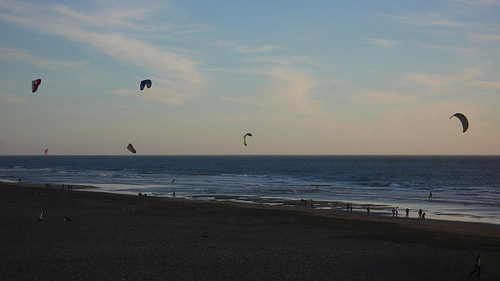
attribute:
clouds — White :
[346, 89, 488, 151]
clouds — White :
[74, 22, 199, 93]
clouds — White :
[9, 2, 165, 38]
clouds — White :
[51, 109, 212, 152]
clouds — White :
[391, 7, 499, 45]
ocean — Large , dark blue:
[1, 151, 499, 227]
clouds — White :
[181, 53, 361, 107]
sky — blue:
[296, 5, 423, 90]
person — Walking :
[400, 204, 412, 216]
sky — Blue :
[169, 27, 382, 92]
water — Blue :
[0, 151, 497, 231]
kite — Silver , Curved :
[242, 131, 252, 146]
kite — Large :
[108, 67, 195, 118]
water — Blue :
[3, 152, 498, 217]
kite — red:
[37, 145, 56, 162]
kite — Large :
[132, 72, 159, 93]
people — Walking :
[130, 187, 440, 226]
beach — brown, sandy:
[5, 179, 498, 279]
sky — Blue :
[2, 6, 495, 150]